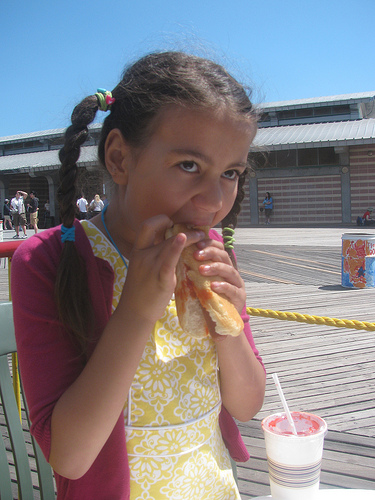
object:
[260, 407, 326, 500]
drink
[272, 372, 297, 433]
straw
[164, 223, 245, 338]
bun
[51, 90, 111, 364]
pigtail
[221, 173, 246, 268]
pigtail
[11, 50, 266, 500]
girl